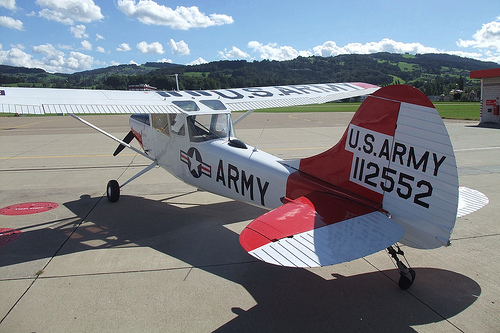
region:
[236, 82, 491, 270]
Tail section of the aircraft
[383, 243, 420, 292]
Tail wheel of the aircraft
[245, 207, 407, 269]
Elevator panel of the aircraft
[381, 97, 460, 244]
Rudder panel of the aircraft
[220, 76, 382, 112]
right wing of the aircraft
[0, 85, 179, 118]
Left wing of the aircraft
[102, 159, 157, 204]
Left main landing gear of the aircraft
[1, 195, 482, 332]
Shadow of the aircraft on the ground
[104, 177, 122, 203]
Left wheel of the main landing gear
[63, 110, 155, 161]
Wing support strut of the aircraft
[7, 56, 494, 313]
white plan with red accents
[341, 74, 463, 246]
black writing on tail wing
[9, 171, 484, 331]
shadow of plane on the ground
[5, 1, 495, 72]
fluffy white clouds in blue sky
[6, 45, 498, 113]
green topped mountains in the distance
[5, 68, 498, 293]
small plane painted white and red with black lettering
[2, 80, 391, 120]
large wing on plane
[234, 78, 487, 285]
tail wing on plane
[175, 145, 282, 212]
black letters on white fuselage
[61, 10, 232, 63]
White clouds in the sky.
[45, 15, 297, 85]
White puffy clouds in the sky.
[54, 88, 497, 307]
U.S. Army plane.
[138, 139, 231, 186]
Star and bars on side of plane.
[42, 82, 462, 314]
Red and white Army plane.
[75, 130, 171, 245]
Landing wheels on airplane.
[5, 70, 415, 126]
Wings on Army airplane.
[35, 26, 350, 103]
Mountains in the distance.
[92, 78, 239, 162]
front of a plane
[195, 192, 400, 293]
wing of a plane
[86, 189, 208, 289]
shadow of a plane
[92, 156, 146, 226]
wheel of a plane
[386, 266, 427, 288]
wheel of a plane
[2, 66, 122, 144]
wing of a plane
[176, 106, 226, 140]
window of a plane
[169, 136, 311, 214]
body of a plane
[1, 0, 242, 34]
THESE ARE WHITE CLOUDS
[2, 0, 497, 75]
THESE ARE THE BLUE SKIES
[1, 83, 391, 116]
THIS IS A WING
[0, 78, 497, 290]
THIS IS A ARMY PLANE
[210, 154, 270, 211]
THIS SAYS THE ARMY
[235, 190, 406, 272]
THIS IS THE LEFT WING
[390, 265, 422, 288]
THATS A WHEEL ON THE PLANE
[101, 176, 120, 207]
THATS THE FRONT WHEEL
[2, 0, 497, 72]
THATS THE BLUE SKY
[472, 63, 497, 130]
THATS A RED BOOTH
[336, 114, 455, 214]
Army writing with plane number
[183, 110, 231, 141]
Window of a plane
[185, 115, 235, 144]
Window of a white plane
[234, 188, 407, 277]
Wing of a plane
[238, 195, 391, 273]
Red and white wing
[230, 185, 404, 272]
Red and white wing of a plane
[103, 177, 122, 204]
Tire of a plane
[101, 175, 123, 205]
Black tire of a plane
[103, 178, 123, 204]
Tire of a white plane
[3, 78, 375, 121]
Large wings of a plane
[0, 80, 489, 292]
a red, white, and blue army propeller plane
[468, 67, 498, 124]
concrete block building with a red roof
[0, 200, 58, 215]
a red manhole cover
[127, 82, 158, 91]
white and red building in the distance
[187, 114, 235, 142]
rear airplane window